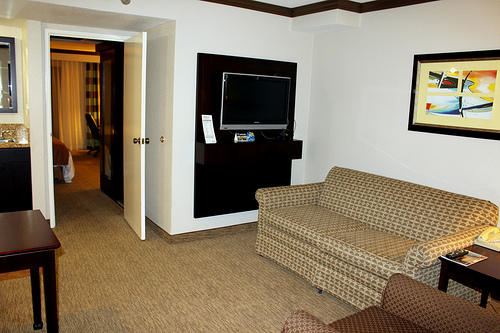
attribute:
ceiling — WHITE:
[198, 0, 443, 23]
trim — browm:
[204, 0, 444, 18]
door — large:
[43, 27, 150, 242]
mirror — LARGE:
[0, 32, 24, 119]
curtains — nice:
[52, 57, 89, 156]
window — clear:
[52, 55, 102, 158]